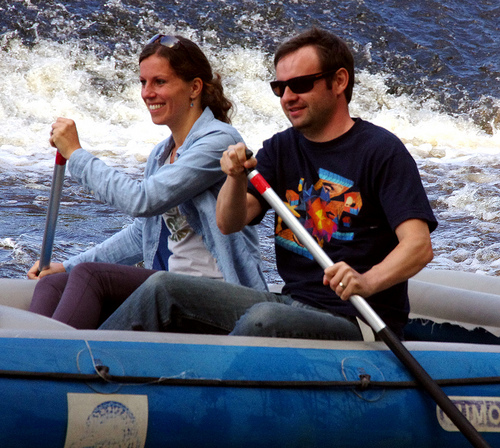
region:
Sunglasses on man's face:
[255, 65, 347, 104]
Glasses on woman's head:
[135, 30, 212, 81]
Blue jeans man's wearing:
[90, 266, 375, 351]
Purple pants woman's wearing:
[15, 257, 157, 329]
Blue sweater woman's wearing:
[59, 116, 274, 300]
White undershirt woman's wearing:
[156, 150, 223, 280]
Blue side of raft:
[2, 332, 498, 444]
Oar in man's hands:
[223, 144, 491, 446]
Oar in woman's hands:
[35, 112, 75, 286]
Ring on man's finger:
[335, 277, 348, 292]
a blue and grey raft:
[0, 270, 497, 436]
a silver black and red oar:
[238, 158, 499, 445]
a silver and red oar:
[37, 143, 64, 262]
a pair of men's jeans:
[91, 268, 355, 335]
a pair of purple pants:
[29, 260, 154, 327]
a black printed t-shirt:
[244, 120, 437, 325]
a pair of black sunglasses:
[265, 74, 322, 96]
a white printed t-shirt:
[158, 151, 218, 276]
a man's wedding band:
[338, 281, 347, 287]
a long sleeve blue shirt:
[57, 105, 269, 285]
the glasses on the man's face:
[264, 68, 331, 99]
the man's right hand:
[212, 139, 263, 177]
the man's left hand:
[317, 258, 374, 303]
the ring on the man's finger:
[336, 277, 348, 291]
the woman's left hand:
[43, 109, 83, 163]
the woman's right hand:
[19, 250, 71, 282]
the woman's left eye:
[150, 74, 168, 88]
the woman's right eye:
[137, 77, 148, 85]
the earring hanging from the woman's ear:
[187, 96, 194, 110]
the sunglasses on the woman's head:
[139, 27, 188, 57]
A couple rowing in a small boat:
[0, 26, 492, 426]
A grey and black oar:
[252, 168, 489, 445]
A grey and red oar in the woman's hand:
[28, 98, 89, 292]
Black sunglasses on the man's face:
[270, 72, 335, 103]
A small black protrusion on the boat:
[360, 373, 379, 397]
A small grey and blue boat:
[31, 302, 498, 446]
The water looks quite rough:
[53, 1, 490, 257]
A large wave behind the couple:
[5, 13, 484, 189]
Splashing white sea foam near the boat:
[7, 42, 475, 163]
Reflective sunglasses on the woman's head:
[135, 27, 198, 61]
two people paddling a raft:
[38, 45, 498, 445]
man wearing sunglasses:
[271, 33, 356, 139]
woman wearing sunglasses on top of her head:
[136, 35, 234, 127]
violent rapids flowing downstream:
[0, 0, 499, 167]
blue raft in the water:
[1, 264, 498, 446]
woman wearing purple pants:
[28, 35, 268, 331]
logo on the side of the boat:
[426, 390, 499, 434]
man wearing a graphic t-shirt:
[215, 26, 419, 338]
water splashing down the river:
[3, 1, 499, 181]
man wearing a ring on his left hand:
[320, 263, 366, 299]